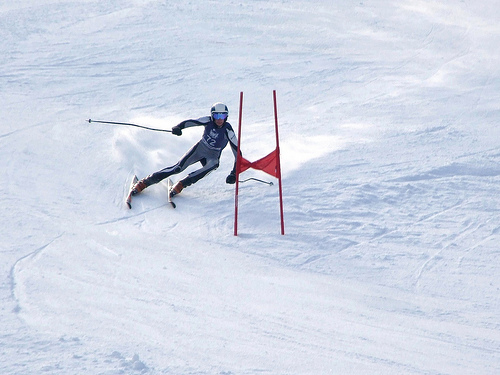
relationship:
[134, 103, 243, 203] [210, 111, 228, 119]
man wearing goggles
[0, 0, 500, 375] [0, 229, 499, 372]
snow on ground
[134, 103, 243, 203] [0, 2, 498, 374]
man skiing down hill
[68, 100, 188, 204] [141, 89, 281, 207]
snow thrown by skier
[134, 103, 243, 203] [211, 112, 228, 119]
man wearing goggles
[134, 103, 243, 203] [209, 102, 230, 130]
man wearing helmet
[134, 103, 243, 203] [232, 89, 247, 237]
man skiing around post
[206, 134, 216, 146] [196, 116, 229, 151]
number on chest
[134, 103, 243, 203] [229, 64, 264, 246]
man skiing around pole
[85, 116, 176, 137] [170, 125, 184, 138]
ski pole in hand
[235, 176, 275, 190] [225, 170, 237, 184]
ski pole in hand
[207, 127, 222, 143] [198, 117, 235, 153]
logo on chest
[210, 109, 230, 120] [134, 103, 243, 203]
blue goggles on man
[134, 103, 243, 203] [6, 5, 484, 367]
man on slope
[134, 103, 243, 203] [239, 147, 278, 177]
man around flag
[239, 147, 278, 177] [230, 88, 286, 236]
flag on poles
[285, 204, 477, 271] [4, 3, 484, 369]
tracks in snow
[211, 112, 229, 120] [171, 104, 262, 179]
blue goggles worn by skier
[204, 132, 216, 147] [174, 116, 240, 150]
number on shirt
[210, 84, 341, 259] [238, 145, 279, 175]
two poles holding flag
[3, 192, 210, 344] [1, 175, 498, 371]
markings in snow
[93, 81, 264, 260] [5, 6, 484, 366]
man skiing slalom